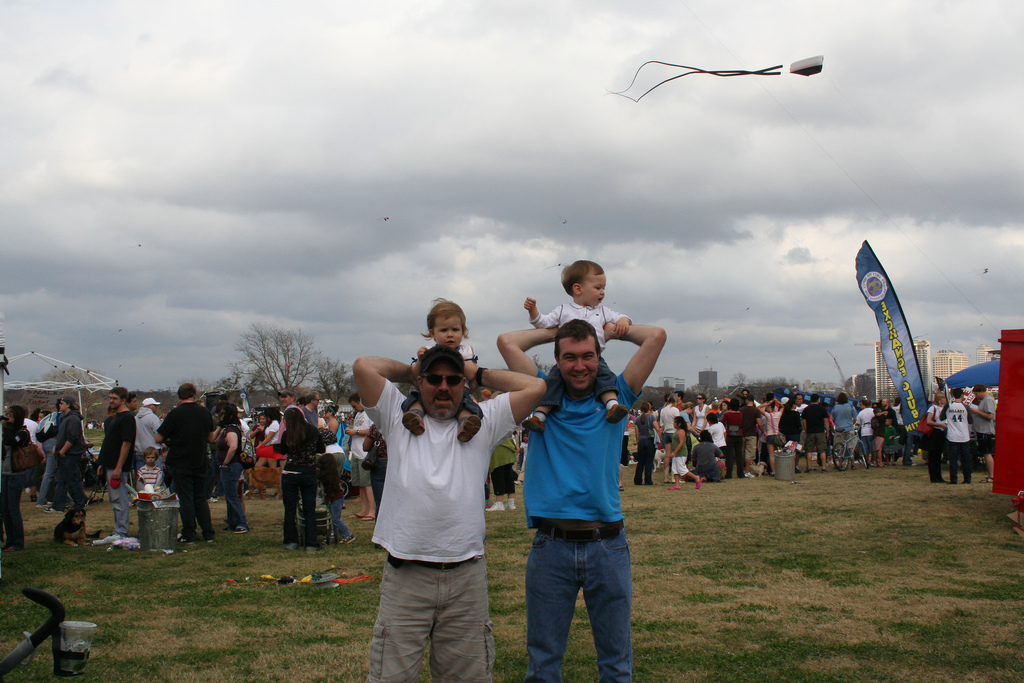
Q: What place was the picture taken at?
A: It was taken at the field.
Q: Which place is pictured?
A: It is a field.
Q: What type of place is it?
A: It is a field.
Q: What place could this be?
A: It is a field.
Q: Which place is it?
A: It is a field.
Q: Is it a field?
A: Yes, it is a field.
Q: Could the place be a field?
A: Yes, it is a field.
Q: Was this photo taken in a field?
A: Yes, it was taken in a field.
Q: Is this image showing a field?
A: Yes, it is showing a field.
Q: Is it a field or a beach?
A: It is a field.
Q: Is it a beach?
A: No, it is a field.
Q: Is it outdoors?
A: Yes, it is outdoors.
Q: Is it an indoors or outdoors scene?
A: It is outdoors.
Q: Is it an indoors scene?
A: No, it is outdoors.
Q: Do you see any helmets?
A: No, there are no helmets.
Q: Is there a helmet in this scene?
A: No, there are no helmets.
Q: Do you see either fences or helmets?
A: No, there are no helmets or fences.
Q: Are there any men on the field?
A: Yes, there is a man on the field.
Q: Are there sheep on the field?
A: No, there is a man on the field.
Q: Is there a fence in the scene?
A: No, there are no fences.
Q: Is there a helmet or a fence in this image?
A: No, there are no fences or helmets.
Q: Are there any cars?
A: No, there are no cars.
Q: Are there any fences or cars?
A: No, there are no cars or fences.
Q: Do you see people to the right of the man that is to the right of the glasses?
A: Yes, there is a person to the right of the man.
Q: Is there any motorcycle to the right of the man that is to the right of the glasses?
A: No, there is a person to the right of the man.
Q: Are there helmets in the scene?
A: No, there are no helmets.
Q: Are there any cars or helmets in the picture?
A: No, there are no helmets or cars.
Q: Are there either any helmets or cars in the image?
A: No, there are no helmets or cars.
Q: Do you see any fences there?
A: No, there are no fences.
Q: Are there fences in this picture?
A: No, there are no fences.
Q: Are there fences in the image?
A: No, there are no fences.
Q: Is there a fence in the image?
A: No, there are no fences.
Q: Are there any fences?
A: No, there are no fences.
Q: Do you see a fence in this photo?
A: No, there are no fences.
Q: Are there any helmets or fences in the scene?
A: No, there are no fences or helmets.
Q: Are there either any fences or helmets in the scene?
A: No, there are no fences or helmets.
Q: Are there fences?
A: No, there are no fences.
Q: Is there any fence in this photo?
A: No, there are no fences.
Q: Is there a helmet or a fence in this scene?
A: No, there are no fences or helmets.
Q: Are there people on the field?
A: Yes, there is a person on the field.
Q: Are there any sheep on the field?
A: No, there is a person on the field.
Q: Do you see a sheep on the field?
A: No, there is a person on the field.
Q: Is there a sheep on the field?
A: No, there is a person on the field.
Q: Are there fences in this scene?
A: No, there are no fences.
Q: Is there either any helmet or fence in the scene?
A: No, there are no fences or helmets.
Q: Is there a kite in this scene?
A: Yes, there is a kite.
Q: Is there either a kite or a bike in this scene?
A: Yes, there is a kite.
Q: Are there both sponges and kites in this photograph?
A: No, there is a kite but no sponges.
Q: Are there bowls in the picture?
A: No, there are no bowls.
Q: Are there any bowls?
A: No, there are no bowls.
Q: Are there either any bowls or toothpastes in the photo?
A: No, there are no bowls or toothpastes.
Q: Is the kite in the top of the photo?
A: Yes, the kite is in the top of the image.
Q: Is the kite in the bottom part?
A: No, the kite is in the top of the image.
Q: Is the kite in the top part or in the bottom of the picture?
A: The kite is in the top of the image.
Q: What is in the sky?
A: The kite is in the sky.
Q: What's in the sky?
A: The kite is in the sky.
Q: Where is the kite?
A: The kite is in the sky.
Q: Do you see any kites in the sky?
A: Yes, there is a kite in the sky.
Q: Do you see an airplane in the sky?
A: No, there is a kite in the sky.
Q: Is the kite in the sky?
A: Yes, the kite is in the sky.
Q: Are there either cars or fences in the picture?
A: No, there are no fences or cars.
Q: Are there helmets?
A: No, there are no helmets.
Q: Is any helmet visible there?
A: No, there are no helmets.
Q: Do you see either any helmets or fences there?
A: No, there are no helmets or fences.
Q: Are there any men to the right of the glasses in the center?
A: Yes, there is a man to the right of the glasses.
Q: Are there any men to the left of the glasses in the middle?
A: No, the man is to the right of the glasses.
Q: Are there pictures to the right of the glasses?
A: No, there is a man to the right of the glasses.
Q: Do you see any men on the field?
A: Yes, there is a man on the field.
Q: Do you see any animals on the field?
A: No, there is a man on the field.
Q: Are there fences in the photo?
A: No, there are no fences.